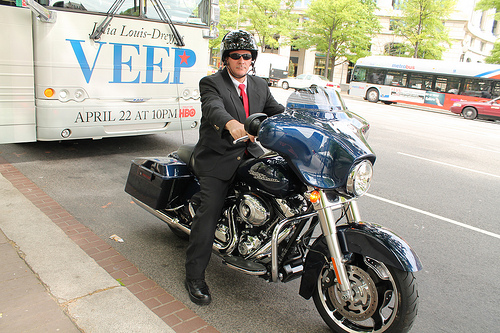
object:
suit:
[181, 69, 289, 288]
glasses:
[228, 52, 252, 60]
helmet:
[223, 28, 259, 63]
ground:
[366, 120, 398, 145]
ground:
[391, 134, 455, 197]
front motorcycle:
[304, 127, 429, 332]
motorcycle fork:
[294, 175, 391, 292]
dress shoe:
[185, 274, 215, 305]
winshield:
[281, 78, 355, 127]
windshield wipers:
[156, 0, 191, 47]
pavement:
[1, 90, 499, 332]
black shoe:
[183, 264, 215, 306]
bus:
[0, 0, 220, 150]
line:
[394, 144, 479, 175]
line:
[352, 194, 499, 243]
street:
[0, 86, 498, 331]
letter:
[74, 111, 83, 123]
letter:
[86, 111, 93, 122]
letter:
[93, 111, 102, 122]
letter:
[103, 111, 107, 121]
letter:
[108, 110, 115, 121]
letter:
[141, 43, 172, 85]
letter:
[134, 111, 142, 120]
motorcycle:
[124, 72, 424, 333]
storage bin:
[122, 155, 200, 210]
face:
[225, 46, 253, 76]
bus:
[346, 52, 500, 119]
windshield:
[49, 0, 227, 27]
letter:
[65, 39, 106, 82]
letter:
[107, 42, 144, 83]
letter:
[169, 46, 196, 84]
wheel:
[300, 220, 422, 331]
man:
[182, 29, 286, 307]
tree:
[286, 3, 379, 82]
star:
[172, 45, 204, 64]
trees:
[254, 0, 295, 55]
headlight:
[342, 154, 373, 198]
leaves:
[332, 14, 356, 34]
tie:
[238, 81, 254, 118]